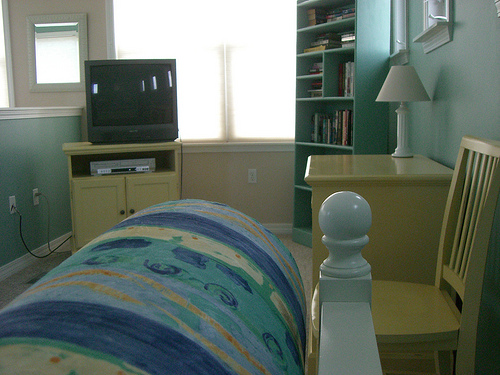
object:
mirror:
[36, 21, 79, 83]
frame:
[29, 13, 88, 92]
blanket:
[3, 200, 305, 371]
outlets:
[32, 189, 42, 207]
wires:
[12, 207, 48, 257]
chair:
[312, 138, 499, 370]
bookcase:
[294, 0, 391, 248]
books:
[347, 61, 354, 98]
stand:
[64, 139, 182, 246]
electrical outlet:
[248, 168, 260, 185]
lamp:
[373, 63, 432, 159]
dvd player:
[88, 159, 156, 174]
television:
[84, 58, 177, 143]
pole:
[321, 192, 371, 303]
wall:
[188, 150, 292, 217]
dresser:
[306, 152, 461, 283]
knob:
[317, 190, 371, 255]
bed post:
[315, 191, 381, 374]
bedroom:
[0, 0, 499, 374]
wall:
[0, 119, 88, 265]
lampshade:
[376, 65, 430, 101]